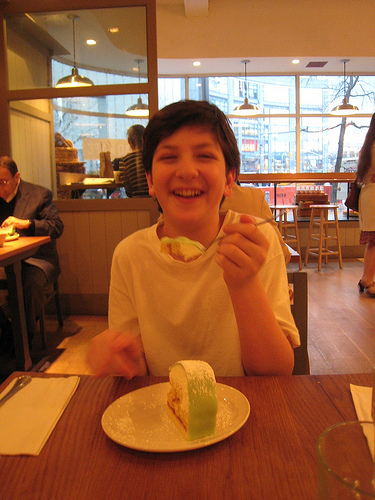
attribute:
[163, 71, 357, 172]
bay window — large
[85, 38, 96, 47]
light — recessed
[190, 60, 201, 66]
light — recessed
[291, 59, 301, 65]
light — recessed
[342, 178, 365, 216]
purse — brown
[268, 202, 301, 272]
stool — Wooden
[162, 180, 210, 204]
smile — big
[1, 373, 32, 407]
utensil — silver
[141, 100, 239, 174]
hair — brown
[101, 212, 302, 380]
shirt — white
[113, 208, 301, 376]
shirt — white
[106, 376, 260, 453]
plate — white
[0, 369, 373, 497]
table — wooden, corner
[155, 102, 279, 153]
hair — short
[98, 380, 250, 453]
plate — white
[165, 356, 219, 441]
cake — slice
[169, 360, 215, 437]
icing — green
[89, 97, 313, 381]
boy — smiling, young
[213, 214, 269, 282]
hand — child's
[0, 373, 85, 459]
napkin — white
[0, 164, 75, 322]
man — elderly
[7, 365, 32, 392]
handle — silver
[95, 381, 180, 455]
sugar — powdered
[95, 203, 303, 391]
t-shirt — white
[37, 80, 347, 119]
lights — drop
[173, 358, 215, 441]
top coat — green